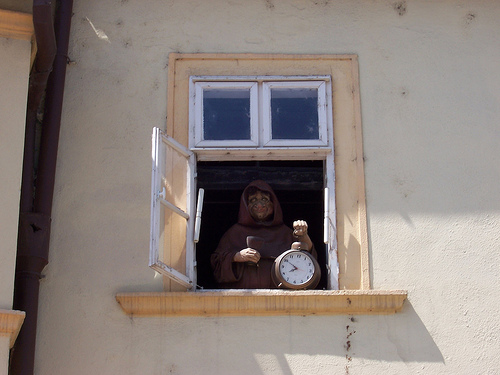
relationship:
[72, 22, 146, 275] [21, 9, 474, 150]
stucco on top of building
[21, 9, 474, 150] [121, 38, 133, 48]
building has a stain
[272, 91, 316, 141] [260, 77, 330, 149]
glass on window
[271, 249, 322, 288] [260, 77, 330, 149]
clock near window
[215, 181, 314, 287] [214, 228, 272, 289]
person wearing a cap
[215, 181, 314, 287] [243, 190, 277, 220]
person wearing a mask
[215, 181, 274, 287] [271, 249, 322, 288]
person holding clock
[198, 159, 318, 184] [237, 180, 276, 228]
cowl above head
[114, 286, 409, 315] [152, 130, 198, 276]
windowsill near window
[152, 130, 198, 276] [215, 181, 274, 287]
window in front of person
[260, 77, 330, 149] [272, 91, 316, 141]
window made of glass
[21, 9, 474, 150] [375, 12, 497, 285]
building has a wall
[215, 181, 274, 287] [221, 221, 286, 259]
person wearing a robe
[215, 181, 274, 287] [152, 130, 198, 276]
person near window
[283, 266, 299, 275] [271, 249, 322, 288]
handle on clock